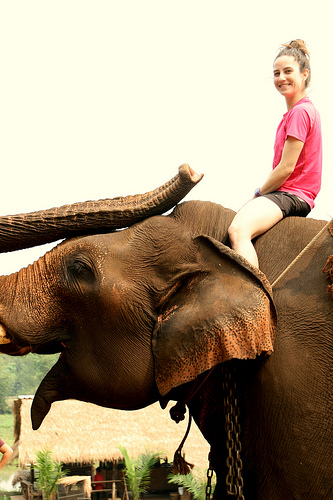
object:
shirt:
[273, 95, 321, 209]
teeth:
[279, 83, 288, 87]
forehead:
[273, 55, 296, 67]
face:
[0, 221, 160, 432]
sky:
[0, 0, 333, 277]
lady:
[225, 35, 322, 273]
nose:
[277, 72, 286, 84]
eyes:
[284, 68, 294, 75]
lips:
[278, 82, 292, 86]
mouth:
[276, 81, 291, 88]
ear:
[152, 227, 278, 398]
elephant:
[0, 163, 333, 500]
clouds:
[0, 0, 333, 271]